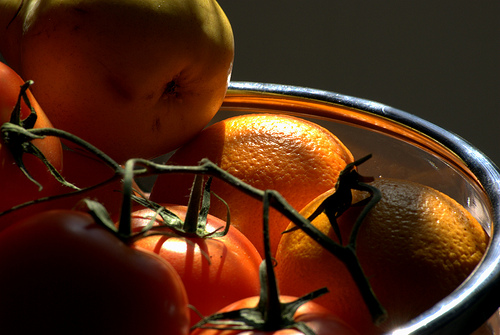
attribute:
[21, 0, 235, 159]
apple — brown, green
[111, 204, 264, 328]
tomato — red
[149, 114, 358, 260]
orange — shiny, food, pitted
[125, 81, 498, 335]
bowl — metal, steel, silver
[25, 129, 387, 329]
vine — threadlike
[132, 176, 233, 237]
leaf — green